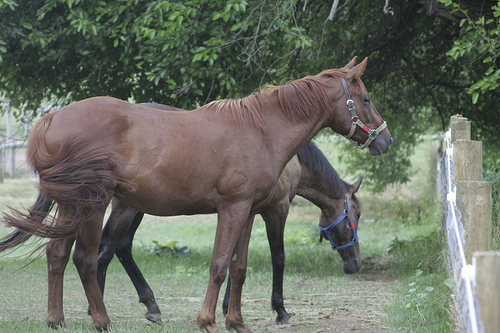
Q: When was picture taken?
A: Daytime.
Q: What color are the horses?
A: Brown.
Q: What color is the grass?
A: Green.